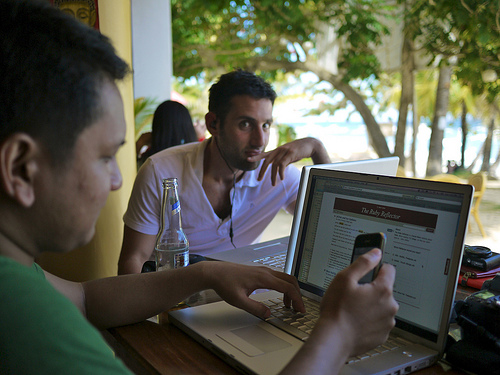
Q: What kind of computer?
A: Laptop.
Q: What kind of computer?
A: Laptop.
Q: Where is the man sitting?
A: Table.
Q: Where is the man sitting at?
A: Table.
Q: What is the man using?
A: Laptop.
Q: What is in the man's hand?
A: Cellphone.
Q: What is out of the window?
A: Tree.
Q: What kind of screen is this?
A: Laptop.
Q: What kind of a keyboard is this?
A: Laptop.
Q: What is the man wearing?
A: Ear plugs.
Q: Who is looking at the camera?
A: Man in white.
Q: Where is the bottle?
A: Near arm.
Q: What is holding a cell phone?
A: Hand.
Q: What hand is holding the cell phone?
A: Right.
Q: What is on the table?
A: Laptops.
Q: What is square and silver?
A: Laptops.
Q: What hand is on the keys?
A: Left.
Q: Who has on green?
A: Closest man.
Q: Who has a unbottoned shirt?
A: Man in white.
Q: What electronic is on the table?
A: Laptop.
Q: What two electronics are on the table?
A: Laptops.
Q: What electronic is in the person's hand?
A: Smartphone.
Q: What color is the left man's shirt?
A: Green.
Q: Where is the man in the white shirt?
A: On the right.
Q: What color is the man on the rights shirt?
A: White.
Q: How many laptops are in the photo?
A: One.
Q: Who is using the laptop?
A: The man.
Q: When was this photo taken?
A: During the day.